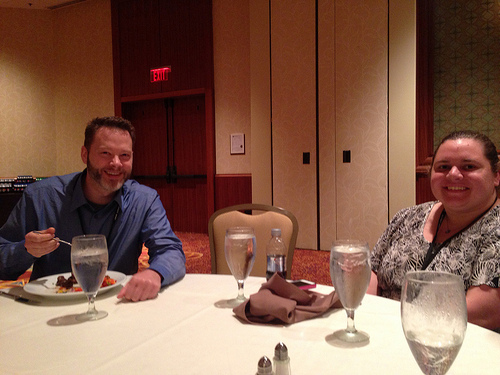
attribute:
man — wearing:
[1, 109, 199, 301]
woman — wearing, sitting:
[363, 131, 500, 324]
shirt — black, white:
[362, 200, 499, 306]